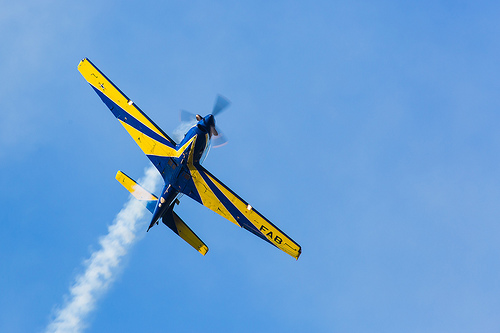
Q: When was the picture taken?
A: Daytime.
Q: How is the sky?
A: Clear and blue.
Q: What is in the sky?
A: A plane.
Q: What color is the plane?
A: Blue and gold.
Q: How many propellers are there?
A: One.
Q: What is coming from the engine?
A: Smoke.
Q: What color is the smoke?
A: White.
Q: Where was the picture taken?
A: At an airshow.